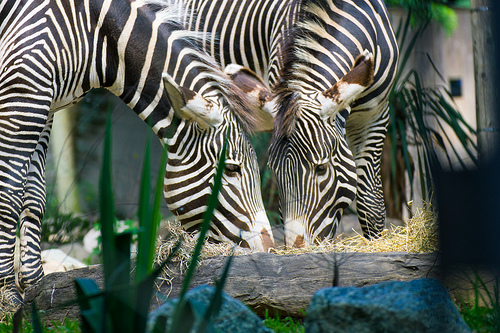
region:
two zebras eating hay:
[0, 0, 421, 271]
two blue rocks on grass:
[155, 272, 450, 322]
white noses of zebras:
[245, 215, 306, 245]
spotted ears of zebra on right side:
[225, 47, 365, 102]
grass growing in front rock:
[16, 125, 228, 315]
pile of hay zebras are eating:
[150, 210, 420, 248]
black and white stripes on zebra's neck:
[94, 12, 199, 119]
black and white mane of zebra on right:
[284, 0, 326, 83]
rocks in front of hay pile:
[23, 252, 428, 314]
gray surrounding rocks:
[33, 306, 483, 330]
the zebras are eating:
[123, 41, 395, 280]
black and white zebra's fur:
[75, 10, 426, 330]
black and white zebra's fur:
[113, 22, 218, 279]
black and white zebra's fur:
[303, 31, 391, 134]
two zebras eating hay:
[153, 51, 378, 268]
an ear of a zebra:
[153, 69, 218, 129]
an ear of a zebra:
[221, 59, 272, 120]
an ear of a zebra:
[321, 48, 377, 120]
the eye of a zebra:
[310, 163, 331, 182]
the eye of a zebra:
[222, 157, 241, 178]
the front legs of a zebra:
[1, 89, 55, 315]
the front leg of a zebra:
[358, 130, 390, 242]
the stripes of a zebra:
[364, 149, 381, 223]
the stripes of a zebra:
[9, 26, 51, 71]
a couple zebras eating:
[175, 56, 378, 278]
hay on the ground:
[180, 225, 434, 259]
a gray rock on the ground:
[61, 235, 453, 315]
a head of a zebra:
[276, 58, 374, 250]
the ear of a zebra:
[166, 85, 232, 145]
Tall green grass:
[47, 139, 248, 324]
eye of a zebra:
[310, 148, 353, 178]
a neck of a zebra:
[85, 23, 230, 125]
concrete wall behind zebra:
[413, 38, 498, 185]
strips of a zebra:
[285, 0, 372, 72]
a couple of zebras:
[166, 20, 404, 246]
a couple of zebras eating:
[160, 81, 357, 256]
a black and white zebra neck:
[95, 25, 206, 85]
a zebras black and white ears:
[235, 50, 390, 140]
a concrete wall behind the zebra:
[405, 35, 485, 185]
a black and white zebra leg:
[15, 32, 75, 302]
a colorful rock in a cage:
[297, 270, 468, 325]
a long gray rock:
[55, 251, 431, 306]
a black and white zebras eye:
[306, 152, 337, 189]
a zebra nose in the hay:
[239, 228, 318, 260]